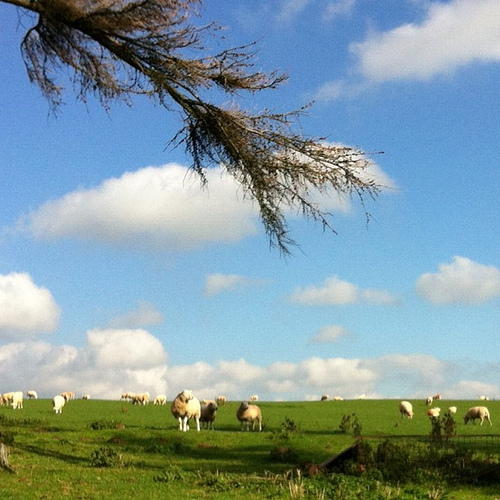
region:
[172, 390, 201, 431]
a tan sheep in field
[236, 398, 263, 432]
a tan sheep in field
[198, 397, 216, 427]
a tan sheep in field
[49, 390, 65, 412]
a tan sheep in field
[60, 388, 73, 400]
a tan sheep in field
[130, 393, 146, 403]
a tan sheep in field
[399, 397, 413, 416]
a tan sheep in field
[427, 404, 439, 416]
a tan sheep in field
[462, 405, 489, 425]
a tan sheep in field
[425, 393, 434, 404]
a tan sheep in field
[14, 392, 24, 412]
sheep has white fleece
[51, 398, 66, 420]
sheep has white fleece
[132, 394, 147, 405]
sheep has white fleece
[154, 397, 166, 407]
sheep has white fleece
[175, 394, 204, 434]
sheep has white fleece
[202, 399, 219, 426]
sheep has white fleece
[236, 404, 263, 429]
sheep has white fleece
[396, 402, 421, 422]
sheep has white fleece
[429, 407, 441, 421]
sheep has white fleece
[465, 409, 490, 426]
sheep has white fleece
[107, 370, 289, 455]
Sheep in a field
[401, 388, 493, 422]
Sheep in a field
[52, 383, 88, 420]
Sheep in a field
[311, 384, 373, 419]
Sheep in a field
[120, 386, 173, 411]
Sheep in a field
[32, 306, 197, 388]
Cloudy sky over a field of sheep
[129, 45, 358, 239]
leaves on a tree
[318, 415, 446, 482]
bushes in the field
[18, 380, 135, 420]
sheep standing together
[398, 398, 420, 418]
sheep grazing pasture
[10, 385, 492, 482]
large green field for sheep to graze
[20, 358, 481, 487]
sheep grazing in a large field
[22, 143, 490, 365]
white clouds scattered in sky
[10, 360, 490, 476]
many white sheep grazing in a field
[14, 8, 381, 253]
tree branche hanging over field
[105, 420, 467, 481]
shadow on ground from tree branch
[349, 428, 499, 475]
small fence in field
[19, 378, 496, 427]
white sheep grazing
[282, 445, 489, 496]
small area of tall grass and bushes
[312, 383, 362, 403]
sheep grazing in the distance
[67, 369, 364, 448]
flock of sheep in a field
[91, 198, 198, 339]
white fluffy clouds in the air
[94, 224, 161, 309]
bright blue sky with clouds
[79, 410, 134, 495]
little bushes on a field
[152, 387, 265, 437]
white sheep in a field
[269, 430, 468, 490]
shadow from a tree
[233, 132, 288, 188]
leaves on a tree branch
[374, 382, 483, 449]
sheep grazing in a field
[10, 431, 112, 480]
shadow from a tree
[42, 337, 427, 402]
trees on the horizon